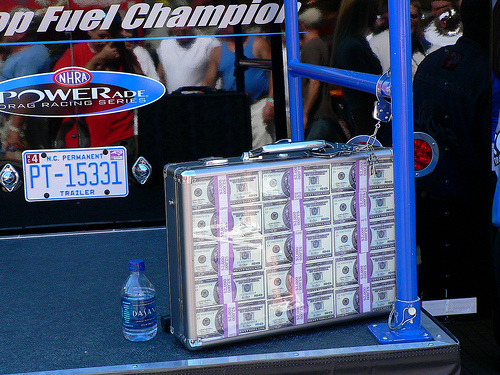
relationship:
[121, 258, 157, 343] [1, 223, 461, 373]
bottle on table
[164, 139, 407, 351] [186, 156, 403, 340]
briefcase full of money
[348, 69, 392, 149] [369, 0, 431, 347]
handcuffs on pole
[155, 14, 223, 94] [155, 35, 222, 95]
man in shirt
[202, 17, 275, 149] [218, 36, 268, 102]
man in shirt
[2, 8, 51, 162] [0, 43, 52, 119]
man in shirt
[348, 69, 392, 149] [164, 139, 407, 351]
handcuffs holding briefcase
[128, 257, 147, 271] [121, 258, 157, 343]
top on bottle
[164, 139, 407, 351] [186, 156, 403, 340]
briefcase with money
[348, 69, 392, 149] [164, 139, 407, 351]
handcuffs securing briefcase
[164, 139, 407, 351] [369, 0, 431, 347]
briefcase attached to pole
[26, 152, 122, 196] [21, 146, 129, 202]
letters on plate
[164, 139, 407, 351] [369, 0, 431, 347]
briefcase secured to pole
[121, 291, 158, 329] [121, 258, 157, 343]
label on bottle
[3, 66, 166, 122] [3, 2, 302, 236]
advertisment on glass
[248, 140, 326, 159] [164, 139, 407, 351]
handle on briefcase